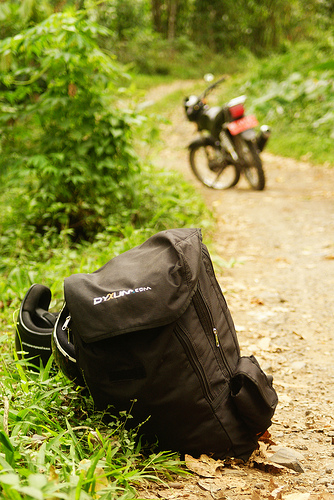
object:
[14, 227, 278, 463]
bag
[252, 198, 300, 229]
road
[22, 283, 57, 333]
cushion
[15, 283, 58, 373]
helmet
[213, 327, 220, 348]
tag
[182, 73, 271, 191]
motorbike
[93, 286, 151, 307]
logo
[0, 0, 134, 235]
bush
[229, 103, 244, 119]
square light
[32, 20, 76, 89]
leaves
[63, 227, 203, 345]
cover